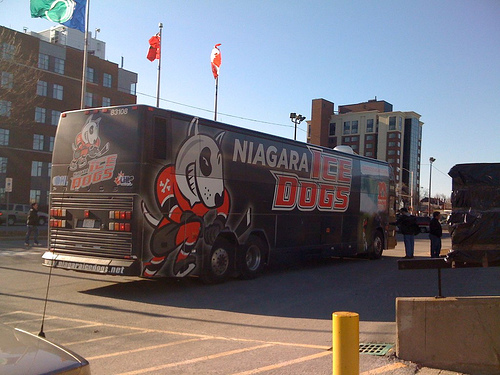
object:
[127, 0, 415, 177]
bad sentance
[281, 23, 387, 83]
clouds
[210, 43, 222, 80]
red design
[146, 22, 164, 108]
flag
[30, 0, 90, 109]
flag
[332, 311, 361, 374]
post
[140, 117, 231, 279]
mascot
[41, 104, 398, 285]
bus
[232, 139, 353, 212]
writting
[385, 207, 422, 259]
man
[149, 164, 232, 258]
uniform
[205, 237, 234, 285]
wheels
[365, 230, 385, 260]
wheels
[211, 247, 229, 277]
silver hub caps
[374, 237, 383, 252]
hub caps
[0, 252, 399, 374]
street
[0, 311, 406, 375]
stripes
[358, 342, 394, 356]
drain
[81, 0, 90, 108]
poles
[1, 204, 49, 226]
suv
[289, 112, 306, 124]
lights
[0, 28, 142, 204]
building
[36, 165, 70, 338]
an antenna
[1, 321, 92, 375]
car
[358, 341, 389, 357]
grate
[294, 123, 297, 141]
pole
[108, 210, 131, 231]
tail lights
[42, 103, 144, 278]
back of the bus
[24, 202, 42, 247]
man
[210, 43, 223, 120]
flag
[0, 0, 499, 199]
sky